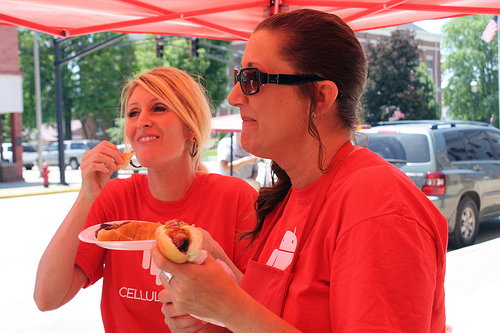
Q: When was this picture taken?
A: Daytime.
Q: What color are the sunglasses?
A: Black.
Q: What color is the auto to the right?
A: Gray.